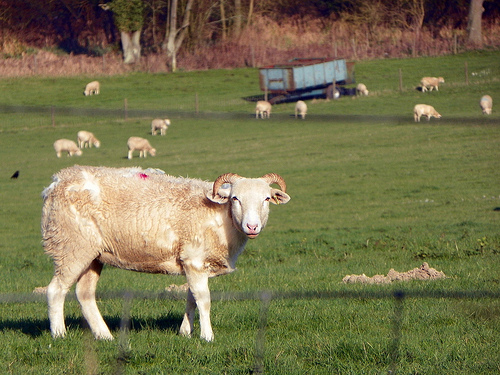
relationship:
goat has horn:
[37, 164, 289, 342] [260, 171, 286, 193]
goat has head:
[37, 164, 289, 342] [205, 172, 292, 238]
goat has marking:
[37, 164, 289, 342] [138, 171, 152, 180]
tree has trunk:
[101, 3, 149, 72] [119, 28, 142, 66]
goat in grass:
[37, 164, 289, 342] [1, 46, 500, 373]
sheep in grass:
[413, 103, 441, 124] [1, 46, 500, 373]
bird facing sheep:
[12, 168, 23, 178] [53, 139, 82, 157]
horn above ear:
[260, 171, 286, 193] [268, 186, 291, 205]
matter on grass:
[341, 261, 447, 284] [1, 46, 500, 373]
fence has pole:
[1, 58, 497, 131] [192, 89, 200, 115]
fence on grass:
[1, 58, 497, 131] [1, 46, 500, 373]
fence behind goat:
[1, 58, 497, 131] [37, 164, 289, 342]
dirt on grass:
[33, 281, 48, 295] [1, 46, 500, 373]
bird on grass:
[12, 168, 23, 178] [1, 46, 500, 373]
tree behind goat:
[101, 3, 149, 72] [37, 164, 289, 342]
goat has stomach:
[37, 164, 289, 342] [95, 244, 183, 277]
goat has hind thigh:
[37, 164, 289, 342] [39, 205, 102, 266]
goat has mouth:
[37, 164, 289, 342] [240, 224, 262, 239]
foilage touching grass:
[2, 0, 498, 79] [1, 46, 500, 373]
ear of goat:
[203, 186, 231, 204] [43, 164, 290, 342]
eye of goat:
[264, 196, 272, 203] [43, 164, 290, 342]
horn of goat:
[260, 171, 286, 193] [43, 164, 290, 342]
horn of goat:
[211, 170, 235, 199] [43, 164, 290, 342]